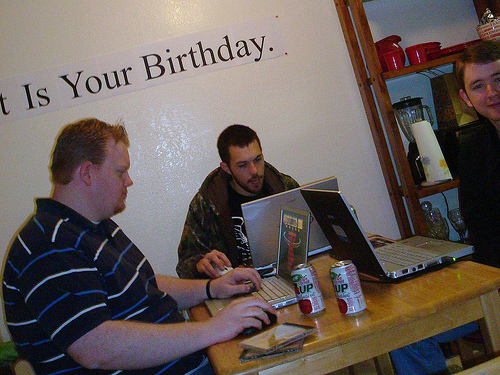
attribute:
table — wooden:
[191, 236, 498, 374]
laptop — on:
[203, 209, 309, 334]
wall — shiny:
[0, 0, 410, 344]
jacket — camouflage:
[174, 165, 300, 279]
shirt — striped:
[3, 199, 213, 374]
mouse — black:
[240, 312, 275, 338]